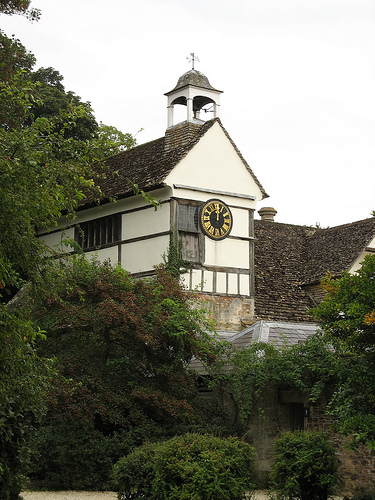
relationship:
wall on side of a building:
[190, 262, 261, 341] [111, 129, 246, 308]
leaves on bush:
[170, 437, 247, 491] [114, 431, 257, 498]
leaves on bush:
[80, 414, 123, 459] [33, 361, 153, 488]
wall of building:
[309, 383, 374, 497] [33, 50, 253, 324]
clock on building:
[200, 198, 231, 238] [32, 53, 373, 488]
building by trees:
[18, 58, 373, 386] [86, 270, 371, 455]